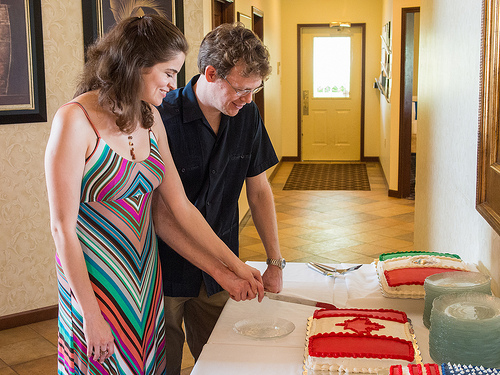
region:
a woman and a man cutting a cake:
[47, 10, 345, 372]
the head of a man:
[193, 24, 271, 118]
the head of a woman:
[90, 2, 189, 112]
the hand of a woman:
[76, 315, 121, 370]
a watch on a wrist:
[263, 254, 291, 269]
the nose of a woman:
[166, 76, 184, 94]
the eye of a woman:
[161, 64, 176, 84]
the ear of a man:
[201, 58, 220, 88]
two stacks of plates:
[412, 272, 496, 363]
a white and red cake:
[301, 299, 422, 370]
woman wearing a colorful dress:
[36, 28, 206, 343]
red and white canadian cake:
[294, 279, 412, 371]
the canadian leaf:
[331, 303, 393, 339]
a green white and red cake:
[379, 232, 474, 303]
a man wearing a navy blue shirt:
[153, 17, 327, 320]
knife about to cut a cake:
[227, 255, 364, 336]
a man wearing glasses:
[221, 75, 284, 110]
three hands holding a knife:
[197, 223, 298, 321]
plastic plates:
[410, 251, 498, 360]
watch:
[259, 245, 294, 272]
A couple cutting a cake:
[41, 6, 433, 373]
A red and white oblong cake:
[301, 289, 420, 374]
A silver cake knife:
[257, 280, 342, 326]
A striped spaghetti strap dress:
[51, 120, 179, 366]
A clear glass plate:
[226, 311, 293, 346]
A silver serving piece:
[312, 259, 362, 286]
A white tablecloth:
[198, 330, 245, 367]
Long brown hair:
[96, 13, 184, 125]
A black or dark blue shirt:
[176, 76, 252, 197]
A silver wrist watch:
[263, 249, 288, 279]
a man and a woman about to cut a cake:
[45, 5, 287, 373]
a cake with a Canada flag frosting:
[305, 305, 420, 372]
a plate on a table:
[233, 315, 294, 339]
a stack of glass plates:
[423, 269, 499, 366]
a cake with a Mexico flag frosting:
[376, 250, 476, 297]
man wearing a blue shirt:
[163, 75, 276, 291]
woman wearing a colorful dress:
[56, 95, 168, 374]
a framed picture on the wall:
[1, 2, 47, 129]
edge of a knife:
[261, 285, 338, 310]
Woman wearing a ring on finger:
[92, 339, 112, 361]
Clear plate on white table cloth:
[227, 309, 301, 351]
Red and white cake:
[298, 294, 426, 373]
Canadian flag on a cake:
[300, 297, 425, 369]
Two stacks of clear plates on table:
[416, 263, 498, 368]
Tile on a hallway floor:
[322, 208, 360, 233]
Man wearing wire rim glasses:
[184, 19, 277, 122]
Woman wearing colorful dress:
[42, 100, 177, 344]